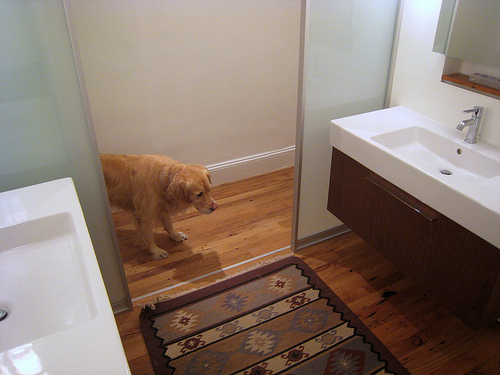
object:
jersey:
[117, 161, 141, 210]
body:
[97, 154, 189, 222]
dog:
[98, 151, 218, 259]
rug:
[137, 251, 411, 375]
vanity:
[396, 1, 491, 98]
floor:
[351, 254, 459, 337]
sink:
[369, 126, 499, 192]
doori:
[6, 29, 72, 124]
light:
[397, 0, 435, 49]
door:
[58, 0, 298, 303]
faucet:
[457, 104, 483, 145]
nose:
[199, 199, 220, 215]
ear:
[165, 177, 195, 203]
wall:
[404, 48, 435, 106]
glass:
[326, 32, 383, 70]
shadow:
[165, 250, 225, 280]